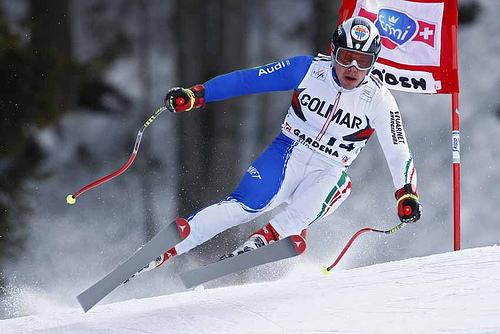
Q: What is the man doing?
A: Skiing.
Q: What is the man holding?
A: Poles.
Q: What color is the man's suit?
A: Blue and white.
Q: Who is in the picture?
A: A man.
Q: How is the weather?
A: Clear.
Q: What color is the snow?
A: White.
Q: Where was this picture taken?
A: A ski slope.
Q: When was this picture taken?
A: Daytime.